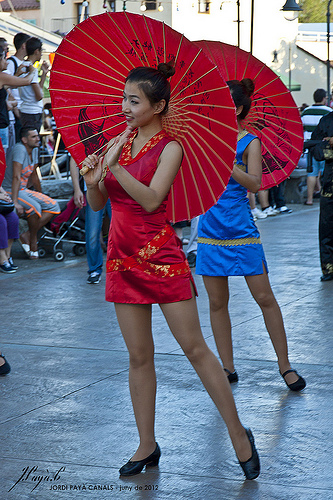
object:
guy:
[69, 156, 111, 285]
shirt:
[2, 140, 35, 190]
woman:
[82, 63, 261, 481]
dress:
[103, 128, 199, 304]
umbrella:
[190, 39, 304, 190]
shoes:
[118, 441, 162, 477]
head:
[122, 65, 171, 127]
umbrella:
[48, 9, 239, 222]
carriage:
[36, 194, 87, 262]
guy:
[12, 128, 61, 260]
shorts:
[6, 187, 61, 217]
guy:
[17, 37, 50, 139]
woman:
[195, 79, 306, 391]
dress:
[195, 128, 270, 275]